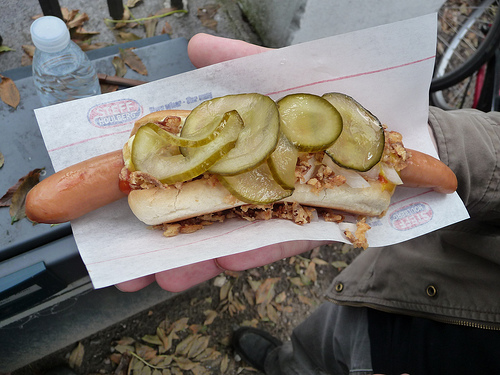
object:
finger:
[115, 240, 339, 293]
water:
[31, 15, 101, 109]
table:
[0, 0, 210, 374]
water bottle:
[28, 16, 102, 107]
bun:
[128, 108, 399, 227]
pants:
[262, 298, 374, 374]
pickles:
[127, 91, 384, 201]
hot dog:
[25, 147, 459, 224]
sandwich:
[27, 91, 465, 218]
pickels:
[120, 87, 419, 208]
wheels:
[421, 0, 500, 113]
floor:
[286, 143, 383, 185]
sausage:
[22, 149, 495, 224]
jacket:
[322, 107, 499, 333]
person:
[113, 31, 500, 374]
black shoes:
[231, 324, 295, 374]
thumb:
[183, 32, 282, 70]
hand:
[113, 29, 438, 293]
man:
[112, 32, 500, 374]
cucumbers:
[130, 92, 387, 206]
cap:
[30, 16, 70, 54]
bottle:
[30, 16, 102, 108]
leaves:
[62, 242, 362, 374]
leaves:
[113, 48, 154, 79]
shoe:
[227, 323, 285, 374]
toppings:
[126, 92, 408, 209]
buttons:
[333, 280, 439, 299]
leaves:
[0, 0, 219, 113]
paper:
[33, 12, 467, 293]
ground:
[99, 301, 227, 374]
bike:
[431, 0, 500, 114]